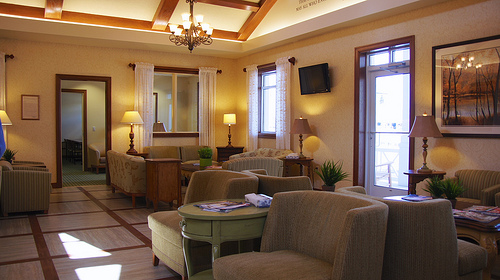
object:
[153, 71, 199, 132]
window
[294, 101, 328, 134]
television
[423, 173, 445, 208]
plant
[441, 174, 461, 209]
plant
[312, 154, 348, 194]
plant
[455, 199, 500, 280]
table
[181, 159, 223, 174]
table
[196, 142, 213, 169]
plant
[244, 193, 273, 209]
tissues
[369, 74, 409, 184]
glass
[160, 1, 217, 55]
lights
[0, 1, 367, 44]
ceiling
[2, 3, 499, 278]
photo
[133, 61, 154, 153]
curatin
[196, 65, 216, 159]
curatin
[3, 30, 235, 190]
wall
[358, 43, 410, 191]
window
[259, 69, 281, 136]
window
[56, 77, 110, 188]
door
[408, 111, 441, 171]
lamp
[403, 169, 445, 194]
table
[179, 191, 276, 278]
table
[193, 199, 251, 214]
magazine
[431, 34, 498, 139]
painting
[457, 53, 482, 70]
light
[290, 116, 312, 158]
lamp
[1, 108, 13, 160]
lamp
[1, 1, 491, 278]
room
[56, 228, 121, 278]
sunlight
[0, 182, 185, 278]
floor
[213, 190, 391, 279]
chair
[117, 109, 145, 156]
lamp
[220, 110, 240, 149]
lamp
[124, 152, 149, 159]
table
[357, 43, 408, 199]
door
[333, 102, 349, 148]
wall